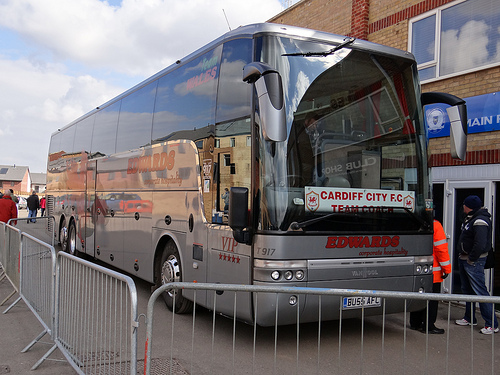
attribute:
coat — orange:
[429, 210, 451, 287]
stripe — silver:
[430, 235, 451, 249]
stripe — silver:
[427, 256, 450, 275]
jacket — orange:
[432, 218, 451, 281]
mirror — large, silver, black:
[444, 106, 470, 156]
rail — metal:
[2, 277, 497, 372]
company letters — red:
[323, 234, 401, 249]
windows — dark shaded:
[387, 0, 496, 88]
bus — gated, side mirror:
[29, 41, 457, 319]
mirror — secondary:
[227, 183, 256, 249]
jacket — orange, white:
[417, 218, 453, 287]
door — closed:
[205, 125, 257, 292]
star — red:
[213, 248, 223, 264]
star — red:
[222, 250, 226, 263]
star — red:
[227, 251, 231, 264]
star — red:
[228, 248, 236, 264]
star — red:
[234, 253, 242, 265]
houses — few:
[0, 166, 46, 206]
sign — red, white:
[301, 180, 423, 225]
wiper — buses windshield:
[280, 35, 352, 62]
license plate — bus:
[341, 292, 383, 305]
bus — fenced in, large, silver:
[41, 24, 436, 324]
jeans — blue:
[456, 260, 498, 330]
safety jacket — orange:
[429, 217, 451, 280]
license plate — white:
[363, 277, 388, 318]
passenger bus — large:
[42, 20, 437, 337]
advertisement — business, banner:
[304, 184, 418, 215]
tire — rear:
[66, 220, 82, 255]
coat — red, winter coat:
[1, 190, 21, 228]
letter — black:
[348, 295, 356, 311]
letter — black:
[365, 294, 373, 306]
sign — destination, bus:
[303, 179, 417, 219]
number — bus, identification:
[336, 298, 386, 305]